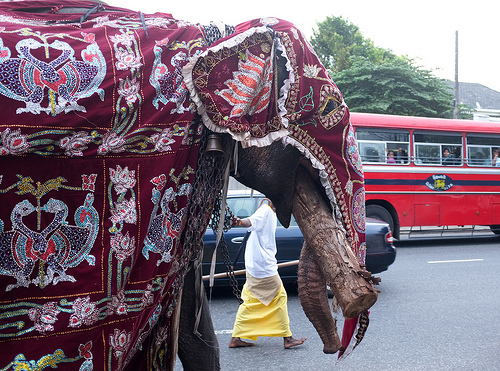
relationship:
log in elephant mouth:
[296, 167, 384, 318] [252, 154, 366, 231]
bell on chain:
[204, 132, 225, 154] [181, 155, 221, 262]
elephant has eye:
[156, 12, 376, 363] [316, 96, 341, 119]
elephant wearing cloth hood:
[76, 20, 404, 357] [187, 15, 377, 359]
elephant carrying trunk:
[156, 12, 376, 363] [294, 236, 343, 356]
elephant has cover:
[156, 12, 376, 363] [171, 58, 247, 115]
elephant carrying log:
[156, 12, 376, 363] [291, 190, 378, 318]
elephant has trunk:
[156, 12, 376, 363] [282, 177, 381, 306]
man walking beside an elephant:
[225, 199, 304, 352] [156, 12, 376, 363]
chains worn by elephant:
[185, 124, 245, 307] [156, 12, 376, 363]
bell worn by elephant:
[204, 132, 227, 157] [156, 12, 376, 363]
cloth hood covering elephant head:
[187, 15, 370, 364] [216, 18, 380, 358]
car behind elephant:
[197, 190, 397, 297] [156, 12, 376, 363]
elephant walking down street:
[156, 12, 376, 363] [202, 219, 495, 369]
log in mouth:
[296, 167, 377, 318] [280, 161, 336, 230]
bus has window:
[346, 111, 498, 245] [409, 129, 466, 167]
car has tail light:
[197, 180, 417, 298] [385, 230, 395, 247]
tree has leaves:
[304, 10, 457, 118] [353, 68, 431, 115]